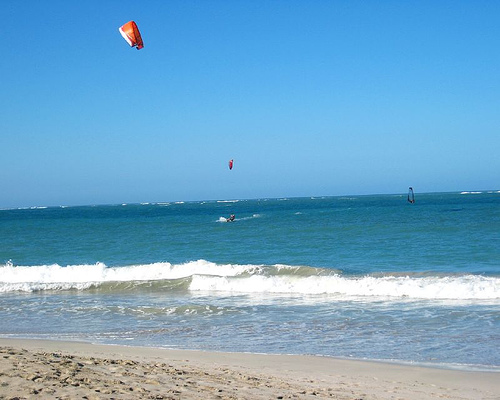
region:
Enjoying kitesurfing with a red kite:
[106, 5, 261, 195]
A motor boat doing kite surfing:
[188, 180, 297, 240]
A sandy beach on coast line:
[5, 317, 345, 392]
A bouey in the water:
[376, 165, 443, 235]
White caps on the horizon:
[19, 187, 261, 215]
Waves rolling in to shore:
[13, 240, 262, 328]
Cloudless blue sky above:
[187, 3, 458, 139]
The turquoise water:
[291, 205, 436, 285]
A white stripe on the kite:
[85, 10, 196, 60]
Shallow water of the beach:
[17, 290, 412, 384]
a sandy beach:
[6, 355, 385, 399]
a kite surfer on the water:
[210, 198, 240, 225]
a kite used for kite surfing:
[113, 16, 148, 57]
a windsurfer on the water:
[404, 183, 418, 210]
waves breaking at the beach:
[1, 253, 498, 322]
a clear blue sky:
[3, 56, 493, 141]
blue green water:
[5, 226, 499, 249]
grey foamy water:
[15, 298, 499, 336]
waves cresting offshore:
[1, 192, 403, 209]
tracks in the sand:
[28, 354, 94, 391]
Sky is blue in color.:
[36, 65, 121, 147]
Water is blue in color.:
[52, 215, 167, 247]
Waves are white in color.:
[7, 250, 202, 297]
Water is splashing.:
[5, 256, 146, 317]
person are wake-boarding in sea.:
[212, 142, 437, 233]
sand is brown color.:
[40, 352, 85, 392]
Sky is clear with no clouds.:
[32, 20, 400, 190]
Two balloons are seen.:
[91, 0, 261, 195]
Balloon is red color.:
[105, 12, 165, 62]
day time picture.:
[33, 29, 455, 372]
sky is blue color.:
[235, 47, 385, 137]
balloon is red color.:
[110, 15, 175, 65]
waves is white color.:
[60, 235, 436, 335]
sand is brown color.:
[25, 350, 110, 395]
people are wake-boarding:
[185, 180, 420, 220]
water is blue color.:
[296, 217, 373, 249]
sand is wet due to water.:
[308, 356, 372, 385]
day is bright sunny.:
[40, 240, 458, 393]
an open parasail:
[107, 18, 168, 63]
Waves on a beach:
[4, 250, 496, 377]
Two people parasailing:
[199, 150, 456, 263]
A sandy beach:
[10, 329, 499, 396]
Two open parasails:
[101, 15, 263, 180]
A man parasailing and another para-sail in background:
[114, 14, 249, 229]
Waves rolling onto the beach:
[6, 253, 499, 385]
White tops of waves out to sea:
[8, 192, 214, 237]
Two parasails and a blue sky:
[103, 18, 262, 182]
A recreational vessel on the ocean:
[381, 180, 498, 259]